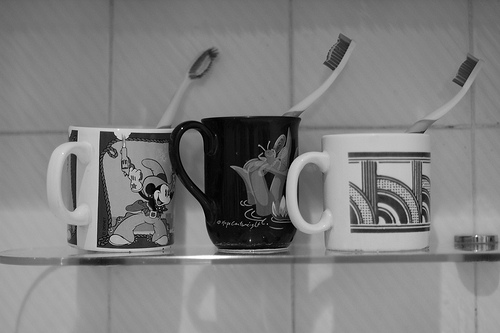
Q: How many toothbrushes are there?
A: Three.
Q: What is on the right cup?
A: Geometric shapes.